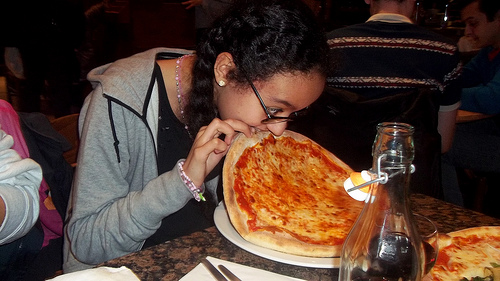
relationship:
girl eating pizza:
[65, 6, 328, 274] [221, 125, 391, 257]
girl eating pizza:
[65, 6, 328, 274] [223, 129, 368, 257]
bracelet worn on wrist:
[179, 163, 205, 201] [171, 159, 199, 204]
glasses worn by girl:
[243, 72, 293, 128] [65, 6, 328, 274]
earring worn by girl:
[214, 80, 237, 93] [65, 6, 328, 274]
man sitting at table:
[334, 4, 462, 168] [434, 90, 494, 142]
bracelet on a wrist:
[178, 163, 202, 200] [172, 146, 206, 196]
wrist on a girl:
[172, 146, 206, 196] [65, 6, 328, 274]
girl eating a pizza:
[65, 6, 328, 274] [221, 125, 391, 257]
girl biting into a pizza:
[65, 6, 328, 274] [221, 125, 391, 257]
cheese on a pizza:
[242, 135, 371, 242] [218, 127, 400, 262]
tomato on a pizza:
[237, 135, 271, 213] [218, 127, 400, 262]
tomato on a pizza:
[438, 222, 488, 262] [429, 220, 498, 278]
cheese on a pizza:
[429, 233, 498, 278] [429, 220, 498, 278]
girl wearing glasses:
[50, 21, 365, 273] [244, 70, 287, 126]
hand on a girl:
[183, 115, 248, 182] [65, 6, 328, 274]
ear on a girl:
[208, 51, 248, 89] [79, 34, 363, 278]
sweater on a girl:
[57, 44, 222, 274] [65, 6, 328, 274]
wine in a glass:
[370, 227, 432, 268] [375, 207, 437, 279]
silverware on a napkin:
[195, 251, 242, 279] [178, 254, 322, 279]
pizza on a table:
[418, 220, 498, 279] [47, 187, 499, 279]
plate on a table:
[212, 203, 339, 271] [1, 185, 498, 278]